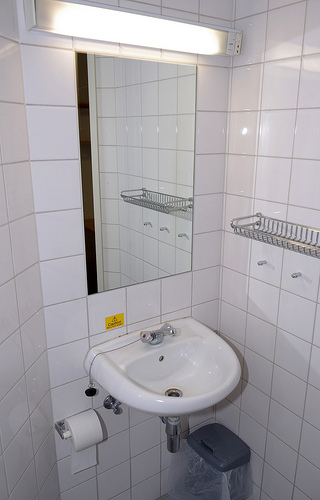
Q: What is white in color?
A: Entire bathroom.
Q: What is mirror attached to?
A: The wall.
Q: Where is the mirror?
A: Over sink.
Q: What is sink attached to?
A: The wall.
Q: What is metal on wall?
A: Shelf.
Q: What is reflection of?
A: The shelf.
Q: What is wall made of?
A: Tiles.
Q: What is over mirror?
A: Light fixture.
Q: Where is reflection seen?
A: In mirror.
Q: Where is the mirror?
A: On wall.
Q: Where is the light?
A: In white holder.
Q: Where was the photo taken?
A: Bathroom.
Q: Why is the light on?
A: Provide light.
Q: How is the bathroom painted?
A: In white.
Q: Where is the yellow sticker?
A: Over the sink.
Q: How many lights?
A: One.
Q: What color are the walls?
A: White.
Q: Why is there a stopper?
A: To plug the sink.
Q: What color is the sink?
A: White.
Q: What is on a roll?
A: Toilet Paper.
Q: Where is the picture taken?
A: Bathroom.